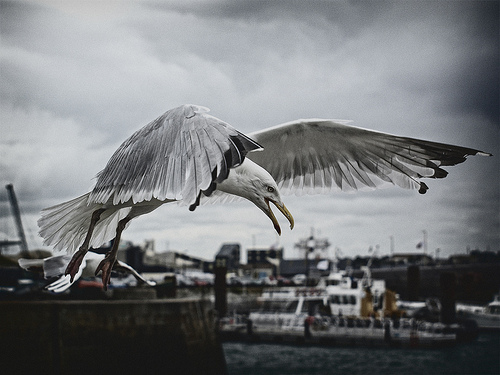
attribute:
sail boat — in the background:
[459, 294, 499, 329]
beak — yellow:
[260, 192, 296, 235]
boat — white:
[240, 281, 462, 345]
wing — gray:
[83, 102, 257, 231]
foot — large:
[48, 235, 93, 296]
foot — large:
[92, 242, 154, 288]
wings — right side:
[98, 100, 262, 217]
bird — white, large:
[111, 92, 238, 178]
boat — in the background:
[231, 253, 496, 353]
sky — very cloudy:
[1, 0, 499, 262]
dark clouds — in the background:
[403, 100, 484, 142]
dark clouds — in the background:
[395, 36, 477, 88]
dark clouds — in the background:
[248, 27, 323, 74]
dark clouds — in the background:
[128, 21, 191, 82]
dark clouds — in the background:
[25, 63, 105, 125]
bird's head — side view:
[231, 161, 296, 236]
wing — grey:
[255, 118, 490, 195]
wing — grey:
[87, 105, 264, 210]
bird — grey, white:
[15, 98, 495, 289]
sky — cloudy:
[0, 0, 492, 239]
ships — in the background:
[246, 274, 456, 341]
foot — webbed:
[72, 243, 148, 289]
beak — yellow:
[259, 193, 297, 245]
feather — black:
[215, 126, 253, 166]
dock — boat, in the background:
[214, 283, 497, 348]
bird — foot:
[14, 98, 493, 347]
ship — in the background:
[264, 283, 390, 344]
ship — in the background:
[329, 273, 447, 341]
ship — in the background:
[420, 285, 498, 336]